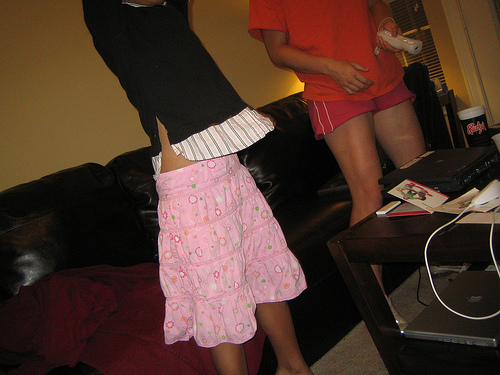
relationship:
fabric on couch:
[2, 264, 266, 374] [6, 92, 453, 373]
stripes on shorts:
[312, 101, 334, 135] [304, 79, 416, 141]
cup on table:
[456, 103, 490, 145] [326, 132, 499, 374]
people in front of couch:
[82, 1, 428, 374] [6, 92, 453, 373]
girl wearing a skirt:
[83, 2, 314, 374] [153, 151, 308, 347]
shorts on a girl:
[304, 79, 416, 141] [247, 3, 425, 331]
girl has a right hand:
[247, 3, 425, 331] [333, 57, 374, 94]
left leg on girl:
[257, 302, 314, 374] [83, 2, 314, 374]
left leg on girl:
[372, 100, 426, 169] [247, 3, 425, 331]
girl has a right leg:
[83, 2, 314, 374] [208, 343, 249, 374]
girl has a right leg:
[247, 3, 425, 331] [322, 112, 382, 293]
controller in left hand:
[375, 29, 420, 55] [377, 23, 402, 51]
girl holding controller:
[247, 3, 425, 331] [375, 29, 420, 55]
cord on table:
[423, 205, 499, 322] [326, 132, 499, 374]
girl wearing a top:
[83, 2, 314, 374] [81, 1, 275, 173]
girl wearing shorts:
[247, 3, 425, 331] [304, 79, 416, 141]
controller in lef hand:
[375, 29, 420, 55] [377, 23, 402, 51]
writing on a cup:
[465, 120, 487, 137] [456, 103, 490, 145]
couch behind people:
[6, 92, 453, 373] [82, 1, 428, 374]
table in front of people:
[326, 132, 499, 374] [82, 1, 428, 374]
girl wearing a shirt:
[247, 3, 425, 331] [248, 2, 406, 103]